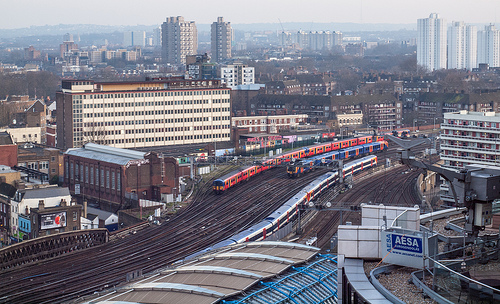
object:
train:
[283, 141, 391, 175]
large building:
[55, 78, 232, 143]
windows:
[154, 100, 163, 106]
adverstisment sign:
[39, 211, 67, 231]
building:
[19, 200, 81, 238]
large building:
[440, 110, 500, 169]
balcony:
[440, 122, 457, 129]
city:
[0, 0, 496, 150]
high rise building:
[160, 16, 196, 72]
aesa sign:
[382, 230, 429, 272]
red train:
[214, 135, 384, 189]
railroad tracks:
[0, 158, 344, 285]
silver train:
[170, 154, 380, 267]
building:
[63, 141, 181, 201]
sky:
[1, 0, 500, 23]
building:
[417, 13, 447, 72]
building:
[344, 201, 500, 302]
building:
[389, 49, 418, 100]